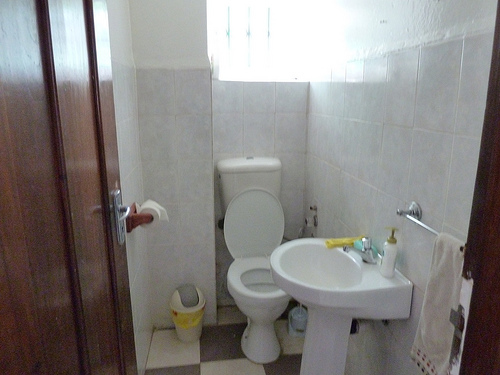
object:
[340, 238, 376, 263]
faucet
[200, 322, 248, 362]
tiles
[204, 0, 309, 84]
window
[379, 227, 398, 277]
bottle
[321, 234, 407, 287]
sink edge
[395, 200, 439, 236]
towel bar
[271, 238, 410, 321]
sink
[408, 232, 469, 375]
towel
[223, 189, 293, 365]
toilet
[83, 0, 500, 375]
bathroom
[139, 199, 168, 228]
paper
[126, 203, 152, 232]
holder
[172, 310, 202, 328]
bag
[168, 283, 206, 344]
can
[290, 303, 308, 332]
brush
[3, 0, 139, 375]
door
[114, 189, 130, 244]
handle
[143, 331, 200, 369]
tile